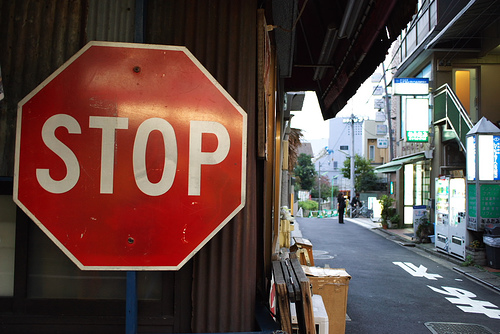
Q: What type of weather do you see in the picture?
A: It is cloudy.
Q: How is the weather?
A: It is cloudy.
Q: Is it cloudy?
A: Yes, it is cloudy.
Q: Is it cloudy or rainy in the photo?
A: It is cloudy.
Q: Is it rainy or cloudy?
A: It is cloudy.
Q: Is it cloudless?
A: No, it is cloudy.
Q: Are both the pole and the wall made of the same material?
A: Yes, both the pole and the wall are made of metal.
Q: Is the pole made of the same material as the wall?
A: Yes, both the pole and the wall are made of metal.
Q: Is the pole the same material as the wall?
A: Yes, both the pole and the wall are made of metal.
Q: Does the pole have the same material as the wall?
A: Yes, both the pole and the wall are made of metal.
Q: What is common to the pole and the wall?
A: The material, both the pole and the wall are metallic.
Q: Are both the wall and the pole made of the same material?
A: Yes, both the wall and the pole are made of metal.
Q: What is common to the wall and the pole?
A: The material, both the wall and the pole are metallic.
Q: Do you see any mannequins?
A: No, there are no mannequins.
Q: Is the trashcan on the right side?
A: Yes, the trashcan is on the right of the image.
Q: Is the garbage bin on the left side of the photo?
A: No, the garbage bin is on the right of the image.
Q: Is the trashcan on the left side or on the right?
A: The trashcan is on the right of the image.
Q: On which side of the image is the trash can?
A: The trash can is on the right of the image.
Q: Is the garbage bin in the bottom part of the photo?
A: Yes, the garbage bin is in the bottom of the image.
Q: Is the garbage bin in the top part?
A: No, the garbage bin is in the bottom of the image.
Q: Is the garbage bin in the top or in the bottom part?
A: The garbage bin is in the bottom of the image.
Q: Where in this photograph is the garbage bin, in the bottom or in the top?
A: The garbage bin is in the bottom of the image.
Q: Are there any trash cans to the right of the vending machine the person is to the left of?
A: Yes, there is a trash can to the right of the vending machine.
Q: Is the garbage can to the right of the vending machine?
A: Yes, the garbage can is to the right of the vending machine.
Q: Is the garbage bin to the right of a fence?
A: No, the garbage bin is to the right of the vending machine.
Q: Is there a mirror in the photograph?
A: No, there are no mirrors.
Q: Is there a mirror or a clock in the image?
A: No, there are no mirrors or clocks.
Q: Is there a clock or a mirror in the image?
A: No, there are no mirrors or clocks.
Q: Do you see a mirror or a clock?
A: No, there are no mirrors or clocks.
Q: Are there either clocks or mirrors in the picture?
A: No, there are no mirrors or clocks.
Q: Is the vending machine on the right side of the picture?
A: Yes, the vending machine is on the right of the image.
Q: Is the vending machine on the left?
A: No, the vending machine is on the right of the image.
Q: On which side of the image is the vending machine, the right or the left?
A: The vending machine is on the right of the image.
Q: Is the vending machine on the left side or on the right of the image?
A: The vending machine is on the right of the image.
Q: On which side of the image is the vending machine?
A: The vending machine is on the right of the image.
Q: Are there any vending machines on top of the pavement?
A: Yes, there is a vending machine on top of the pavement.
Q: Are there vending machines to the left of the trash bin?
A: Yes, there is a vending machine to the left of the trash bin.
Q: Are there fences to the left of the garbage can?
A: No, there is a vending machine to the left of the garbage can.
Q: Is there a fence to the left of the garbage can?
A: No, there is a vending machine to the left of the garbage can.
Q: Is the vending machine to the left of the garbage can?
A: Yes, the vending machine is to the left of the garbage can.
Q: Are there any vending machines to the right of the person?
A: Yes, there is a vending machine to the right of the person.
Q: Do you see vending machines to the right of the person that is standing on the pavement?
A: Yes, there is a vending machine to the right of the person.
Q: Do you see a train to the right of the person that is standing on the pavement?
A: No, there is a vending machine to the right of the person.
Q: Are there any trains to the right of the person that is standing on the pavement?
A: No, there is a vending machine to the right of the person.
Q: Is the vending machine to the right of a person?
A: Yes, the vending machine is to the right of a person.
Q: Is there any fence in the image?
A: No, there are no fences.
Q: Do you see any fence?
A: No, there are no fences.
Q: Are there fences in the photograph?
A: No, there are no fences.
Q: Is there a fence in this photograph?
A: No, there are no fences.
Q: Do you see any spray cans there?
A: No, there are no spray cans.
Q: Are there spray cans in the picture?
A: No, there are no spray cans.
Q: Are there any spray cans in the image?
A: No, there are no spray cans.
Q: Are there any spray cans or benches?
A: No, there are no spray cans or benches.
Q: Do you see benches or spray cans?
A: No, there are no spray cans or benches.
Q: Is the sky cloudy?
A: Yes, the sky is cloudy.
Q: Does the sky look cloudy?
A: Yes, the sky is cloudy.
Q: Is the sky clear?
A: No, the sky is cloudy.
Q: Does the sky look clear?
A: No, the sky is cloudy.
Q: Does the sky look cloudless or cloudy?
A: The sky is cloudy.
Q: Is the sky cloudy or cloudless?
A: The sky is cloudy.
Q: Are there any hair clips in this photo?
A: No, there are no hair clips.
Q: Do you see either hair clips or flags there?
A: No, there are no hair clips or flags.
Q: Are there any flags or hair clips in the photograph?
A: No, there are no hair clips or flags.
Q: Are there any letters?
A: Yes, there are letters.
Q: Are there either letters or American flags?
A: Yes, there are letters.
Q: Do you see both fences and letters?
A: No, there are letters but no fences.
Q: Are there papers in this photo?
A: No, there are no papers.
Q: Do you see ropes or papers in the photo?
A: No, there are no papers or ropes.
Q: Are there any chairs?
A: No, there are no chairs.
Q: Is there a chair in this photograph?
A: No, there are no chairs.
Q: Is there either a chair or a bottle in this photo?
A: No, there are no chairs or bottles.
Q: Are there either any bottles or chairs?
A: No, there are no chairs or bottles.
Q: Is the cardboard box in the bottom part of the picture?
A: Yes, the box is in the bottom of the image.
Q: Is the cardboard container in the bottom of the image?
A: Yes, the box is in the bottom of the image.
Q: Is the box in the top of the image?
A: No, the box is in the bottom of the image.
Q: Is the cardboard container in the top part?
A: No, the box is in the bottom of the image.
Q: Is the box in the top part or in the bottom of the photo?
A: The box is in the bottom of the image.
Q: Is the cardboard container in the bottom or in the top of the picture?
A: The box is in the bottom of the image.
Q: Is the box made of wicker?
A: No, the box is made of cardboard.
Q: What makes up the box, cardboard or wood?
A: The box is made of cardboard.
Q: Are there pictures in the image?
A: No, there are no pictures.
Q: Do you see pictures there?
A: No, there are no pictures.